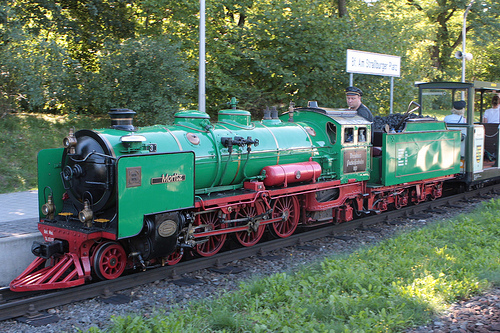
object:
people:
[444, 99, 467, 123]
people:
[484, 94, 499, 123]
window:
[420, 88, 468, 123]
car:
[8, 80, 500, 291]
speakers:
[455, 51, 472, 60]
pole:
[460, 0, 474, 100]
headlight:
[62, 133, 77, 148]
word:
[161, 173, 182, 183]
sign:
[345, 49, 400, 77]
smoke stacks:
[107, 107, 138, 131]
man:
[344, 86, 374, 142]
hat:
[345, 86, 364, 96]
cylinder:
[257, 161, 322, 186]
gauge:
[295, 171, 300, 180]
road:
[0, 183, 45, 292]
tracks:
[0, 180, 499, 329]